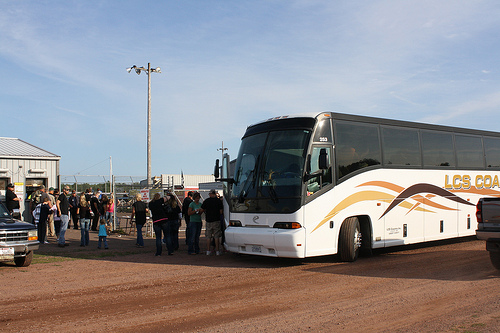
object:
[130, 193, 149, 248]
person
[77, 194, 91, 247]
person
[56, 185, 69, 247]
person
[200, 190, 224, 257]
person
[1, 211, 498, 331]
ground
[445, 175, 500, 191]
lettering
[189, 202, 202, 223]
shirt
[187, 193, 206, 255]
woman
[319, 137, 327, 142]
white number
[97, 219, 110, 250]
girl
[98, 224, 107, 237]
shirt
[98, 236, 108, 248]
jeans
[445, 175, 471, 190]
lcs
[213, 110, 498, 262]
bus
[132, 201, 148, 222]
shirt